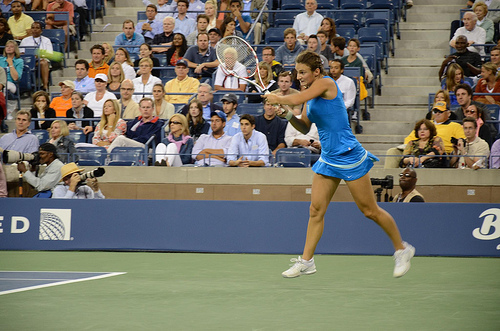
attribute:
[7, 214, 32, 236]
letter — white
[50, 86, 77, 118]
shirt — orange 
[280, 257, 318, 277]
shoe — new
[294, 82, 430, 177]
shirt — yellow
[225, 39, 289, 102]
racket — white, red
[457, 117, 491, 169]
person — happy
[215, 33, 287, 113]
racket — for tennis